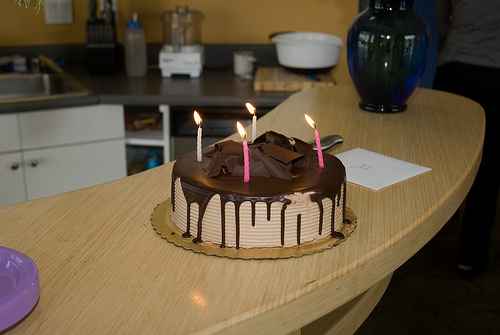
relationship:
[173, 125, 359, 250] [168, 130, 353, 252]
birthday cake in chocolate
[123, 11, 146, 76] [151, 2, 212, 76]
baby bottle by food processor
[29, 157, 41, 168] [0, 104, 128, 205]
hardware on cabinet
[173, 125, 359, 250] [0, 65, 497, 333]
birthday cake on table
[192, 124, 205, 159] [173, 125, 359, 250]
candle on birthday cake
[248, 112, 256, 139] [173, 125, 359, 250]
candle on birthday cake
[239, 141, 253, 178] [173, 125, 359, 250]
candle on birthday cake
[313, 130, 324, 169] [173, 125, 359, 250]
candle on birthday cake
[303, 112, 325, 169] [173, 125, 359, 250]
candle on birthday cake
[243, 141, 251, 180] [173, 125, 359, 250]
candle on birthday cake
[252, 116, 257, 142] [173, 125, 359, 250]
candle on birthday cake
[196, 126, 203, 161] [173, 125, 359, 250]
candle on birthday cake